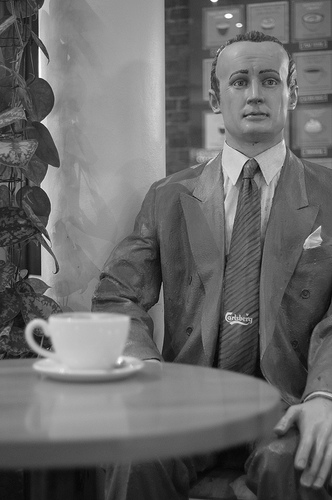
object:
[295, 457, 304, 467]
fingernail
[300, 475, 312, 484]
fingernail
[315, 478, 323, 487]
fingernail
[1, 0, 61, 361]
leaves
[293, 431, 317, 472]
finger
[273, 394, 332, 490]
hand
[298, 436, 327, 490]
finger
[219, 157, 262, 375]
tie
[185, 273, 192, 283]
button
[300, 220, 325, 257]
napkin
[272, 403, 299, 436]
finger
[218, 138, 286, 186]
collar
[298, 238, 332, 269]
pocket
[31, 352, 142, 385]
plate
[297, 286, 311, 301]
button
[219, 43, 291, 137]
face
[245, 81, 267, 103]
nose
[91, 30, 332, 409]
man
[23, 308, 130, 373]
cup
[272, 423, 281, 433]
fingernail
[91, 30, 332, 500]
statue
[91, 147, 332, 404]
jacket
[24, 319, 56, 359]
handle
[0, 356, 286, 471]
table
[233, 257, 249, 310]
stripes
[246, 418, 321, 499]
knee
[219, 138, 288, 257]
shirt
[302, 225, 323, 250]
paper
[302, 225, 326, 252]
handkerchief